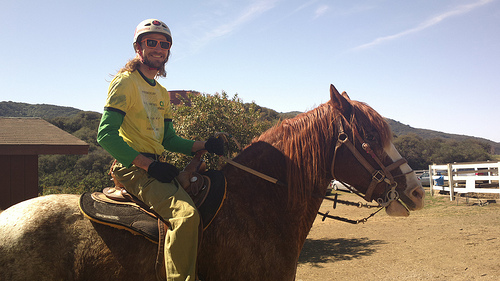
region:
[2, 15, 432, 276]
man riding a horse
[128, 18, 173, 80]
man wearing a white helmet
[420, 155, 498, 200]
white wood fence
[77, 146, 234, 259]
black blanket under the saddle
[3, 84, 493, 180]
brown mountains in the background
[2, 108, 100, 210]
side of brown building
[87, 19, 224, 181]
man wearing long sleeve green shirt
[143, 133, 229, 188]
pair of black gloves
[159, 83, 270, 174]
a green bush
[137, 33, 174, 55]
a pair of orange sunglasses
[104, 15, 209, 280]
this is a person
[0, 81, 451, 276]
the person is on a horse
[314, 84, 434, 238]
the head of a horse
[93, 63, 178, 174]
this is a yellow shirt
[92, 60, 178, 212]
this is a hand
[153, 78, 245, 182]
this is a hand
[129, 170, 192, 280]
this is a leg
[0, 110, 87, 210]
this is a house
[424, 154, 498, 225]
this is a fence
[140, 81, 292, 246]
this is a tree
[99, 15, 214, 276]
this is a man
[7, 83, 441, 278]
this is a horse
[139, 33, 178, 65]
the man is in specs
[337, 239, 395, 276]
dirt on the ground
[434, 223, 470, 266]
dirt on the ground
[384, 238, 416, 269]
dirt on the ground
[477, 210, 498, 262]
dirt on the ground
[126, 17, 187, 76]
Man wearing a white helmet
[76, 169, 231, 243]
The saddle pad is black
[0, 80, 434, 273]
The horse is a red roan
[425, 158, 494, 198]
The fence is white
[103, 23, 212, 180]
The man is wearing a yellow and green shirt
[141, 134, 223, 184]
The gloves are black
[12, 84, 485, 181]
Green mountains behind the rider and horse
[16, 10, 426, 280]
The man is riding a horse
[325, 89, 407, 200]
The halter is brown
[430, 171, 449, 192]
Blue bin on fence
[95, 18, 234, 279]
man sitting on a horse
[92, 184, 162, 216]
man sitting on a saddle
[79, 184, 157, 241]
saddle blanket under saddle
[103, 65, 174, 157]
yellow t shirt on man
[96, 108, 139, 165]
green long sleeves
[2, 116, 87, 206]
brown building behind horse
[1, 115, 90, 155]
roof on building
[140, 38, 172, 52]
man wearing sunglasses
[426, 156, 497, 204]
white wooden fence behind horse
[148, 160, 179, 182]
man wearing black gloves